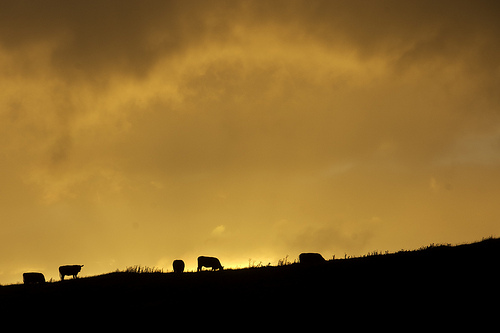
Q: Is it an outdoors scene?
A: Yes, it is outdoors.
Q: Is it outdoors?
A: Yes, it is outdoors.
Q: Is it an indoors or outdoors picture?
A: It is outdoors.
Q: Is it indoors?
A: No, it is outdoors.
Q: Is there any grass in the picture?
A: Yes, there is grass.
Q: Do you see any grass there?
A: Yes, there is grass.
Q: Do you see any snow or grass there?
A: Yes, there is grass.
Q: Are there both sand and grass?
A: No, there is grass but no sand.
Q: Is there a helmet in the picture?
A: No, there are no helmets.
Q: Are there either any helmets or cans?
A: No, there are no helmets or cans.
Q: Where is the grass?
A: The grass is on the hill.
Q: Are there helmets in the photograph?
A: No, there are no helmets.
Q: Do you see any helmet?
A: No, there are no helmets.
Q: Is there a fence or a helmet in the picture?
A: No, there are no helmets or fences.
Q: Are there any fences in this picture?
A: No, there are no fences.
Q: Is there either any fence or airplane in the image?
A: No, there are no fences or airplanes.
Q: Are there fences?
A: No, there are no fences.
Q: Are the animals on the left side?
A: Yes, the animals are on the left of the image.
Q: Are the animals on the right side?
A: No, the animals are on the left of the image.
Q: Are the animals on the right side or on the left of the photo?
A: The animals are on the left of the image.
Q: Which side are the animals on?
A: The animals are on the left of the image.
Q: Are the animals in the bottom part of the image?
A: Yes, the animals are in the bottom of the image.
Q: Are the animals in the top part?
A: No, the animals are in the bottom of the image.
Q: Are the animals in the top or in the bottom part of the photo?
A: The animals are in the bottom of the image.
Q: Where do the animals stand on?
A: The animals stand on the hill.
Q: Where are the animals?
A: The animals are on the hill.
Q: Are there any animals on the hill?
A: Yes, there are animals on the hill.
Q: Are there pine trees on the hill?
A: No, there are animals on the hill.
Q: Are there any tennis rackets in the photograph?
A: No, there are no tennis rackets.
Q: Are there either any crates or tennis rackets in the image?
A: No, there are no tennis rackets or crates.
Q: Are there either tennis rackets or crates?
A: No, there are no tennis rackets or crates.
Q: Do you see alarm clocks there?
A: No, there are no alarm clocks.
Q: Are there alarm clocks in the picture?
A: No, there are no alarm clocks.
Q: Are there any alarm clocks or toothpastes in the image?
A: No, there are no alarm clocks or toothpastes.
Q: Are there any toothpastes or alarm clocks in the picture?
A: No, there are no alarm clocks or toothpastes.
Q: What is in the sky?
A: The clouds are in the sky.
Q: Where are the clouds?
A: The clouds are in the sky.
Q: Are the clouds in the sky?
A: Yes, the clouds are in the sky.